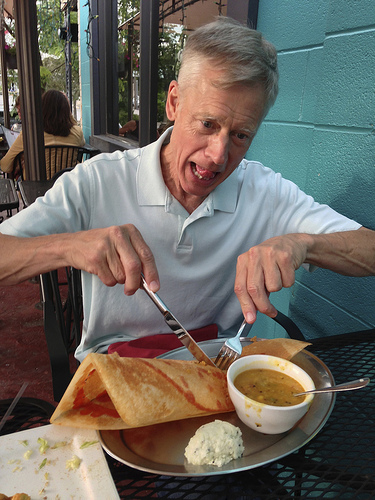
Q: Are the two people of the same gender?
A: No, they are both male and female.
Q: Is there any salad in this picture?
A: Yes, there is salad.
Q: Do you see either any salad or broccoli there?
A: Yes, there is salad.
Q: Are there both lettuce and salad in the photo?
A: No, there is salad but no lettuce.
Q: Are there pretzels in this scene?
A: No, there are no pretzels.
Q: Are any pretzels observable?
A: No, there are no pretzels.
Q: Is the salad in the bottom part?
A: Yes, the salad is in the bottom of the image.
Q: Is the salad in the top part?
A: No, the salad is in the bottom of the image.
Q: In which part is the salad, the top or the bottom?
A: The salad is in the bottom of the image.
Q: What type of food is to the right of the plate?
A: The food is salad.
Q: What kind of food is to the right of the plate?
A: The food is salad.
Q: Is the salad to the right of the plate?
A: Yes, the salad is to the right of the plate.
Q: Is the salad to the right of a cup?
A: No, the salad is to the right of the plate.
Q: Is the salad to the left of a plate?
A: No, the salad is to the right of a plate.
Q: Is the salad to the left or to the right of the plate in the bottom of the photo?
A: The salad is to the right of the plate.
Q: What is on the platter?
A: The salad is on the platter.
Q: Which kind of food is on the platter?
A: The food is salad.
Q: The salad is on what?
A: The salad is on the platter.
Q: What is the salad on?
A: The salad is on the platter.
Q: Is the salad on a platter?
A: Yes, the salad is on a platter.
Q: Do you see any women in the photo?
A: Yes, there is a woman.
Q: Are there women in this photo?
A: Yes, there is a woman.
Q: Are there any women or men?
A: Yes, there is a woman.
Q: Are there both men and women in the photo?
A: Yes, there are both a woman and men.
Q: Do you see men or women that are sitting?
A: Yes, the woman is sitting.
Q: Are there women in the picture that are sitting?
A: Yes, there is a woman that is sitting.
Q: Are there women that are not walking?
A: Yes, there is a woman that is sitting.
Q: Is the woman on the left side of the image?
A: Yes, the woman is on the left of the image.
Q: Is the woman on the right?
A: No, the woman is on the left of the image.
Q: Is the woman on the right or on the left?
A: The woman is on the left of the image.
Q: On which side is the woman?
A: The woman is on the left of the image.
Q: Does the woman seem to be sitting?
A: Yes, the woman is sitting.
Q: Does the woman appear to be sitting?
A: Yes, the woman is sitting.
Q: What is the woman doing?
A: The woman is sitting.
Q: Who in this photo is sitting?
A: The woman is sitting.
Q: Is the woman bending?
A: No, the woman is sitting.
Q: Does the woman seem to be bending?
A: No, the woman is sitting.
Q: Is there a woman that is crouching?
A: No, there is a woman but she is sitting.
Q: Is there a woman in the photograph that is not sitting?
A: No, there is a woman but she is sitting.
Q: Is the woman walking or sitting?
A: The woman is sitting.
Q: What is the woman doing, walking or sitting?
A: The woman is sitting.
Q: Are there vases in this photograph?
A: No, there are no vases.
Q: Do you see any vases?
A: No, there are no vases.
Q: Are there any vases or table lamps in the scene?
A: No, there are no vases or table lamps.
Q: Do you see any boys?
A: No, there are no boys.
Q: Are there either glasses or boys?
A: No, there are no boys or glasses.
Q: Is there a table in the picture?
A: Yes, there is a table.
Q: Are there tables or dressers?
A: Yes, there is a table.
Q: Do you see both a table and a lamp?
A: No, there is a table but no lamps.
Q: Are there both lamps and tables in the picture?
A: No, there is a table but no lamps.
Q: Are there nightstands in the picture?
A: No, there are no nightstands.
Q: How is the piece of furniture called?
A: The piece of furniture is a table.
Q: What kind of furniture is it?
A: The piece of furniture is a table.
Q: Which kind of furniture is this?
A: This is a table.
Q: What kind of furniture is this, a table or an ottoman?
A: This is a table.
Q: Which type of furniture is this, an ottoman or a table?
A: This is a table.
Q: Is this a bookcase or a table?
A: This is a table.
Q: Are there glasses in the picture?
A: No, there are no glasses.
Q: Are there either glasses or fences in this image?
A: No, there are no glasses or fences.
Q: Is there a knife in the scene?
A: Yes, there is a knife.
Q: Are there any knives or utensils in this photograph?
A: Yes, there is a knife.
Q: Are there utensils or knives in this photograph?
A: Yes, there is a knife.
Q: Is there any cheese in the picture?
A: No, there is no cheese.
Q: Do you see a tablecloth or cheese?
A: No, there are no cheese or tablecloths.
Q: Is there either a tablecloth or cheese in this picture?
A: No, there are no cheese or tablecloths.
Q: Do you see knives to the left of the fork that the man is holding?
A: Yes, there is a knife to the left of the fork.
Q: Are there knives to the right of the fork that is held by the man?
A: No, the knife is to the left of the fork.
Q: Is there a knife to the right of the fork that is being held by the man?
A: No, the knife is to the left of the fork.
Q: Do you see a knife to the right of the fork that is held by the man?
A: No, the knife is to the left of the fork.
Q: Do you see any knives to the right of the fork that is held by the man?
A: No, the knife is to the left of the fork.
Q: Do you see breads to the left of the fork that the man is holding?
A: No, there is a knife to the left of the fork.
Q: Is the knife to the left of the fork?
A: Yes, the knife is to the left of the fork.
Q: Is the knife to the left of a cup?
A: No, the knife is to the left of the fork.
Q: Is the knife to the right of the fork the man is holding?
A: No, the knife is to the left of the fork.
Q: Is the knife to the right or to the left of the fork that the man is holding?
A: The knife is to the left of the fork.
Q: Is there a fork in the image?
A: Yes, there is a fork.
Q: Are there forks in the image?
A: Yes, there is a fork.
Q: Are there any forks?
A: Yes, there is a fork.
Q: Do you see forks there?
A: Yes, there is a fork.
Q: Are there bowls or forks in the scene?
A: Yes, there is a fork.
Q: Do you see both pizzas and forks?
A: No, there is a fork but no pizzas.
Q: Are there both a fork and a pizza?
A: No, there is a fork but no pizzas.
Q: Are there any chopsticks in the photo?
A: No, there are no chopsticks.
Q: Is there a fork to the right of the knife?
A: Yes, there is a fork to the right of the knife.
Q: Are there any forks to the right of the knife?
A: Yes, there is a fork to the right of the knife.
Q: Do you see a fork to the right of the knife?
A: Yes, there is a fork to the right of the knife.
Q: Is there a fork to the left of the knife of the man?
A: No, the fork is to the right of the knife.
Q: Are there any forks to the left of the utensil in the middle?
A: No, the fork is to the right of the knife.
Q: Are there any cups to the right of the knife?
A: No, there is a fork to the right of the knife.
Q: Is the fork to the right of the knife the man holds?
A: Yes, the fork is to the right of the knife.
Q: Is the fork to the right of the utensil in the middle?
A: Yes, the fork is to the right of the knife.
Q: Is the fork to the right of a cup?
A: No, the fork is to the right of the knife.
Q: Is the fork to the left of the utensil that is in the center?
A: No, the fork is to the right of the knife.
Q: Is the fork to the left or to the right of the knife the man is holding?
A: The fork is to the right of the knife.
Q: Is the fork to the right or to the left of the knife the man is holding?
A: The fork is to the right of the knife.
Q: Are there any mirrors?
A: No, there are no mirrors.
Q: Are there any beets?
A: No, there are no beets.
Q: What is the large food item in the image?
A: The food item is a tortilla.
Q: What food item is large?
A: The food item is a tortilla.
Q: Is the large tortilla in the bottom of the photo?
A: Yes, the tortilla is in the bottom of the image.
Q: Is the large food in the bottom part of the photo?
A: Yes, the tortilla is in the bottom of the image.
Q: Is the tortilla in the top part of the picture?
A: No, the tortilla is in the bottom of the image.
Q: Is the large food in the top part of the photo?
A: No, the tortilla is in the bottom of the image.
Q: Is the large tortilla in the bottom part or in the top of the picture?
A: The tortilla is in the bottom of the image.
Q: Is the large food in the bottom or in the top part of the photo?
A: The tortilla is in the bottom of the image.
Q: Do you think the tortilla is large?
A: Yes, the tortilla is large.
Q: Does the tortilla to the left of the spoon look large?
A: Yes, the tortilla is large.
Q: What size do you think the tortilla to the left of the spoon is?
A: The tortilla is large.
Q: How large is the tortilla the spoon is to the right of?
A: The tortilla is large.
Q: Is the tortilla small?
A: No, the tortilla is large.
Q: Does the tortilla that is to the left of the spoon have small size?
A: No, the tortilla is large.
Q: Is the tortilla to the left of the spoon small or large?
A: The tortilla is large.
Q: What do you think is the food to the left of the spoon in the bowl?
A: The food is a tortilla.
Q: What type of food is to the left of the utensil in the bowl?
A: The food is a tortilla.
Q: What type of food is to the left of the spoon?
A: The food is a tortilla.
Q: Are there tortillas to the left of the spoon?
A: Yes, there is a tortilla to the left of the spoon.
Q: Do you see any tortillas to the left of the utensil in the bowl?
A: Yes, there is a tortilla to the left of the spoon.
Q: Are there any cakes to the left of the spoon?
A: No, there is a tortilla to the left of the spoon.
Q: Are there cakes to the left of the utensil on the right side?
A: No, there is a tortilla to the left of the spoon.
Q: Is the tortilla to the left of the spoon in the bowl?
A: Yes, the tortilla is to the left of the spoon.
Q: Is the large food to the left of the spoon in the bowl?
A: Yes, the tortilla is to the left of the spoon.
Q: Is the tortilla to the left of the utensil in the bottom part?
A: Yes, the tortilla is to the left of the spoon.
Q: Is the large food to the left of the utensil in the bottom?
A: Yes, the tortilla is to the left of the spoon.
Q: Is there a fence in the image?
A: No, there are no fences.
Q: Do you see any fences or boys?
A: No, there are no fences or boys.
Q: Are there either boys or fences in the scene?
A: No, there are no fences or boys.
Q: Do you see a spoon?
A: Yes, there is a spoon.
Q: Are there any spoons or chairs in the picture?
A: Yes, there is a spoon.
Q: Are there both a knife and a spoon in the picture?
A: Yes, there are both a spoon and a knife.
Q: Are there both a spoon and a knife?
A: Yes, there are both a spoon and a knife.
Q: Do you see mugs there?
A: No, there are no mugs.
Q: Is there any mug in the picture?
A: No, there are no mugs.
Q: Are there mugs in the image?
A: No, there are no mugs.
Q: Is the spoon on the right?
A: Yes, the spoon is on the right of the image.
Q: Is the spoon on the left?
A: No, the spoon is on the right of the image.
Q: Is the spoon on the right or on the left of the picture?
A: The spoon is on the right of the image.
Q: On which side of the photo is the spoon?
A: The spoon is on the right of the image.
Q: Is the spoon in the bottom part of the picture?
A: Yes, the spoon is in the bottom of the image.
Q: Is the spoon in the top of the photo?
A: No, the spoon is in the bottom of the image.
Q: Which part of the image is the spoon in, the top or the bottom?
A: The spoon is in the bottom of the image.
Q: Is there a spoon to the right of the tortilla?
A: Yes, there is a spoon to the right of the tortilla.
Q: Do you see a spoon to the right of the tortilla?
A: Yes, there is a spoon to the right of the tortilla.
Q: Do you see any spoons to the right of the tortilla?
A: Yes, there is a spoon to the right of the tortilla.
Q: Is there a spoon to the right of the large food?
A: Yes, there is a spoon to the right of the tortilla.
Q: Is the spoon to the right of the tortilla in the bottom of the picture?
A: Yes, the spoon is to the right of the tortilla.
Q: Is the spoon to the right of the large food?
A: Yes, the spoon is to the right of the tortilla.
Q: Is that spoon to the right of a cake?
A: No, the spoon is to the right of the tortilla.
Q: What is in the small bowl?
A: The spoon is in the bowl.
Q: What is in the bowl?
A: The spoon is in the bowl.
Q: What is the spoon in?
A: The spoon is in the bowl.